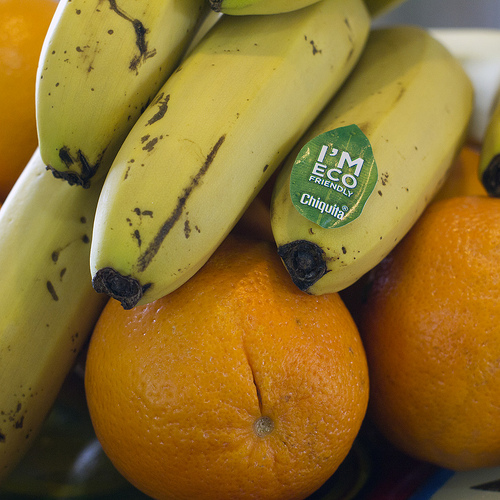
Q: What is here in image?
A: Fruits.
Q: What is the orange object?
A: Orange.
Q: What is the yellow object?
A: Banana.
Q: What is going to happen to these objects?
A: Get eaten.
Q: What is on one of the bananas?
A: Sticker.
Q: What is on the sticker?
A: I'm Eco Friendly.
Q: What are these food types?
A: Fruit.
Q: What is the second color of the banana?
A: Black.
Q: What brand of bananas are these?
A: Chiquita.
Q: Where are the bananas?
A: On top of the oranges.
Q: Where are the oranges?
A: Beneath the bananas.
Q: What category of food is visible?
A: Fruit.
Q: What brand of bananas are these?
A: Chiquita.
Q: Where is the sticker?
A: On a banana.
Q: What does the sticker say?
A: I'm Eco Friendly.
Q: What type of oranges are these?
A: Navel.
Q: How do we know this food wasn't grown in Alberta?
A: Warm weather fruits.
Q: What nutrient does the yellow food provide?
A: Potassium.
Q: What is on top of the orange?
A: Banana.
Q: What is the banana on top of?
A: Orange.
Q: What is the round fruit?
A: Orange.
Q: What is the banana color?
A: Yellow.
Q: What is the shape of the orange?
A: Round.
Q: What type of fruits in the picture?
A: Oranges and bananas.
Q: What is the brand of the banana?
A: Chiquita.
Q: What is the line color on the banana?
A: Brown.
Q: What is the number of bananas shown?
A: Four.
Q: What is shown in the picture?
A: Fruit.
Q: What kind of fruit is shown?
A: Oranges and bananas.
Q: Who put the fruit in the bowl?
A: The homeowner.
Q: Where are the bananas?
A: On top of the oranges.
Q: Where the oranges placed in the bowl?
A: First.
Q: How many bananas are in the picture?
A: Six.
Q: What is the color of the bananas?
A: Yellow.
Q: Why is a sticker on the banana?
A: To identify the distributor.